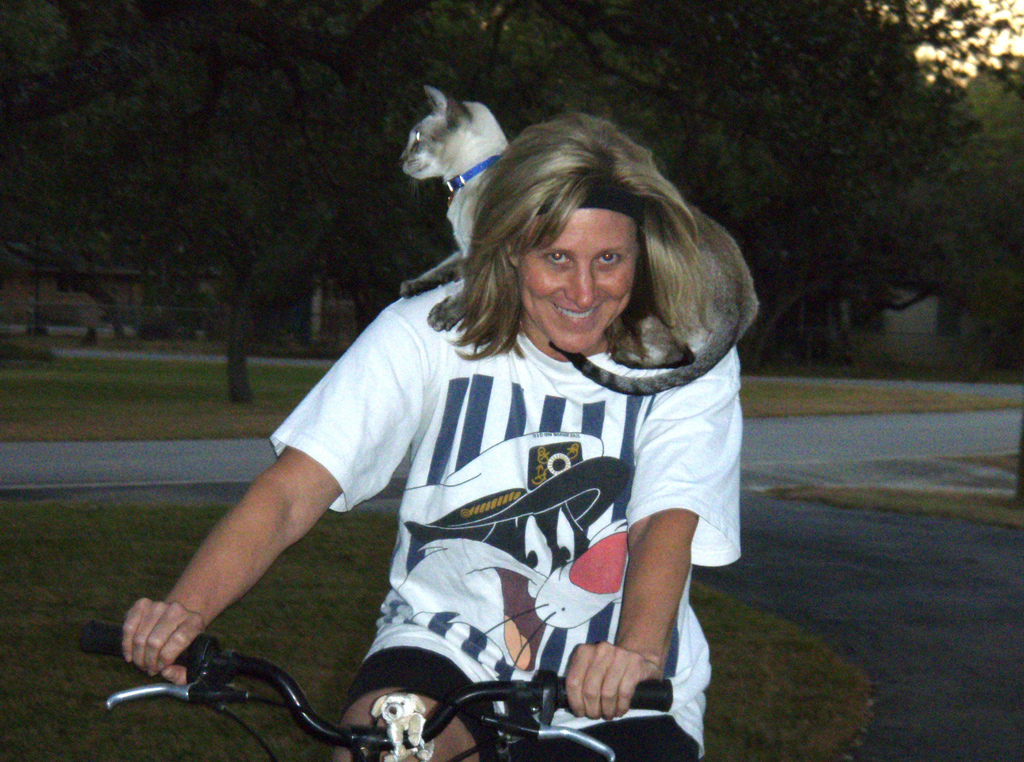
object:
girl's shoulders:
[381, 278, 746, 436]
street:
[699, 487, 1022, 762]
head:
[429, 115, 709, 364]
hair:
[638, 181, 714, 369]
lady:
[120, 84, 758, 760]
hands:
[121, 596, 219, 684]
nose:
[570, 531, 628, 594]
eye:
[414, 131, 420, 142]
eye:
[599, 253, 621, 265]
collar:
[441, 154, 504, 194]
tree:
[0, 0, 1013, 406]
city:
[0, 1, 1021, 759]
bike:
[77, 622, 699, 758]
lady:
[120, 113, 747, 761]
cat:
[395, 84, 760, 393]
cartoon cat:
[402, 433, 632, 678]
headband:
[536, 185, 646, 225]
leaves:
[819, 50, 877, 104]